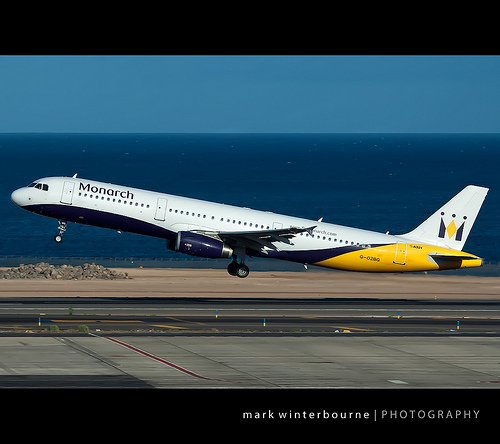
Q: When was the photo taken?
A: Daytime.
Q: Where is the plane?
A: On a runway, taking off.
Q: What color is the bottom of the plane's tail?
A: Yellow.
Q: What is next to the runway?
A: A body of blue water.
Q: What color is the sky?
A: It is blue.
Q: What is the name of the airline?
A: Monarch.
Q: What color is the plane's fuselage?
A: White.